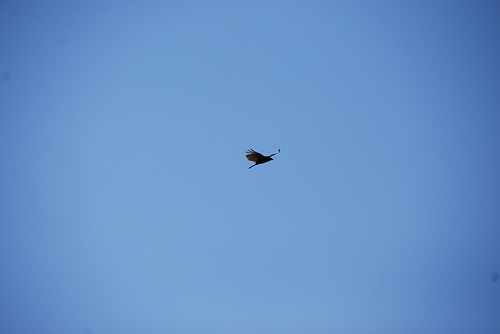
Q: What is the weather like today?
A: It is cloudless.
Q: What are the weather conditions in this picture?
A: It is cloudless.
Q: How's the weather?
A: It is cloudless.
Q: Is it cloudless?
A: Yes, it is cloudless.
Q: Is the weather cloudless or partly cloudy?
A: It is cloudless.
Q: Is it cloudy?
A: No, it is cloudless.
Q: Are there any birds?
A: Yes, there is a bird.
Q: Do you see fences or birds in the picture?
A: Yes, there is a bird.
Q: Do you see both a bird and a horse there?
A: No, there is a bird but no horses.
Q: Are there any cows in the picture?
A: No, there are no cows.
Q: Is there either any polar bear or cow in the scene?
A: No, there are no cows or polar bears.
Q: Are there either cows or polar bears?
A: No, there are no cows or polar bears.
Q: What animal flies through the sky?
A: The animal is a bird.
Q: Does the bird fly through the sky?
A: Yes, the bird flies through the sky.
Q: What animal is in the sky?
A: The bird is in the sky.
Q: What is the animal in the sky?
A: The animal is a bird.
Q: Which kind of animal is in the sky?
A: The animal is a bird.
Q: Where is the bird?
A: The bird is in the sky.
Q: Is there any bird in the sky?
A: Yes, there is a bird in the sky.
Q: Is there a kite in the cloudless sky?
A: No, there is a bird in the sky.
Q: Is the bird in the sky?
A: Yes, the bird is in the sky.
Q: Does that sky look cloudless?
A: Yes, the sky is cloudless.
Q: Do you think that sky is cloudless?
A: Yes, the sky is cloudless.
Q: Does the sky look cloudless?
A: Yes, the sky is cloudless.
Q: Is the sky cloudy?
A: No, the sky is cloudless.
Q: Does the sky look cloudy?
A: No, the sky is cloudless.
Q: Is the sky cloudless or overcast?
A: The sky is cloudless.